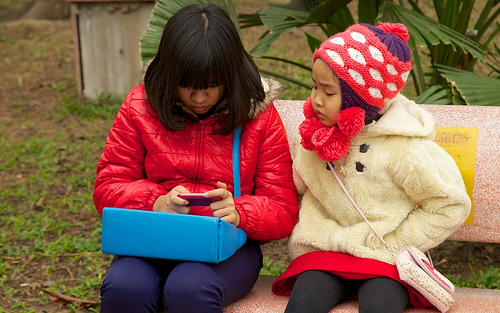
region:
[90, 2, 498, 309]
two girls seated together on a bench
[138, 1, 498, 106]
section of a large green plant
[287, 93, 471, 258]
girl is wearing a furry white jacket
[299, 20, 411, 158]
large woven hat tied beneath girl's chin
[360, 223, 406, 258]
girl's hand is in her pocket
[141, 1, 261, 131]
girl's dark hair is falling forward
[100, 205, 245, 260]
blue purse on girl's lap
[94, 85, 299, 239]
a zipped-up red jacket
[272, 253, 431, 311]
girl is wearing a red skirt over black leggings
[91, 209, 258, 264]
blue purse on lap of woman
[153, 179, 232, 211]
pink cellphone being held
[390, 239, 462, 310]
tan and punk purse around neck of child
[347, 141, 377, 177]
black buttons on shirt of child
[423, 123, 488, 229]
yellow sign on back of bench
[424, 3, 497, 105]
large green leaves on plant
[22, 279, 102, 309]
brown leaf laying on ground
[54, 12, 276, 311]
woman with long brown hair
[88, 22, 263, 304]
this is a girl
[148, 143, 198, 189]
the jacket is red in color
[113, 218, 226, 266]
this is a bag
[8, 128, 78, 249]
this is a grass area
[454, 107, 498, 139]
this is a bench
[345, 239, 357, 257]
pat of a coat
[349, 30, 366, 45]
white dot on hat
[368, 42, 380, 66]
white dot on hat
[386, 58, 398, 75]
white dot on hat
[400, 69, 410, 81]
white dot on hat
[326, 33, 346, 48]
white dot on hat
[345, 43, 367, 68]
white dot on hat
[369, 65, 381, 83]
white dot on hat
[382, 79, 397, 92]
white dot on hat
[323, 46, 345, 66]
white dot on hat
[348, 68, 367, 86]
white dot on hat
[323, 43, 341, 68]
white polka dot on the red hat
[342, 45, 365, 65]
white polka dot on the red hat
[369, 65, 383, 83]
white polka dot on the red hat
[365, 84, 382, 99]
white polka dot on the red hat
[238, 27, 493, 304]
a girl sittin gon bench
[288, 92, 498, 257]
a girl ewaring a coat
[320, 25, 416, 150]
a girl wearing a hat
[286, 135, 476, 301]
a girl with abag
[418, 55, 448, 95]
green leaves on the plant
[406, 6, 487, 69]
green leaves on the plant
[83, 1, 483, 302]
Two little girls sitting on a bench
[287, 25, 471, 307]
A girl with Her hands tucked in her pocket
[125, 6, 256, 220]
A girl looking at her cell phone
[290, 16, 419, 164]
A little girl wearing a knitted hat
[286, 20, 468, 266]
A little girl wearing a white jacket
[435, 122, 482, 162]
A yellow sign on the back of the bench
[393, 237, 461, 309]
The little girl's purse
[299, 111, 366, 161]
Pom-poms from the Knitted hat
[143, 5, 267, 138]
Little girl with black hair